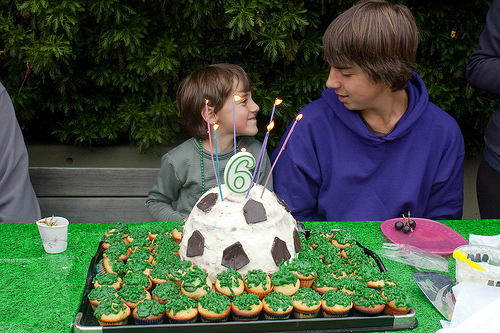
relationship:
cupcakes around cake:
[87, 229, 413, 315] [179, 183, 300, 272]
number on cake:
[223, 151, 255, 195] [179, 183, 300, 272]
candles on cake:
[203, 95, 303, 199] [179, 183, 300, 272]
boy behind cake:
[144, 61, 273, 220] [179, 183, 300, 272]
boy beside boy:
[144, 61, 273, 220] [272, 1, 464, 221]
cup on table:
[34, 215, 69, 252] [1, 220, 498, 332]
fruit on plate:
[395, 211, 414, 234] [375, 214, 468, 255]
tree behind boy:
[1, 0, 499, 150] [144, 61, 273, 220]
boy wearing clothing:
[272, 1, 464, 221] [273, 70, 465, 219]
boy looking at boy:
[144, 61, 273, 220] [272, 1, 464, 221]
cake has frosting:
[179, 183, 300, 272] [182, 184, 300, 273]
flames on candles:
[201, 91, 305, 153] [203, 95, 303, 199]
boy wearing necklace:
[144, 61, 273, 220] [196, 137, 208, 192]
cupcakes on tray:
[87, 229, 413, 315] [74, 234, 418, 331]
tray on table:
[74, 234, 418, 331] [1, 220, 498, 332]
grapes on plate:
[395, 211, 414, 234] [375, 214, 468, 255]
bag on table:
[381, 239, 449, 275] [1, 220, 498, 332]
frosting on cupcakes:
[90, 227, 409, 317] [87, 229, 413, 315]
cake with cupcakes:
[179, 183, 300, 272] [87, 229, 413, 315]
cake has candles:
[179, 183, 300, 272] [203, 95, 303, 199]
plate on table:
[375, 214, 468, 255] [1, 220, 498, 332]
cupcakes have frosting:
[87, 229, 413, 315] [90, 227, 409, 317]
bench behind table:
[28, 168, 157, 223] [1, 220, 498, 332]